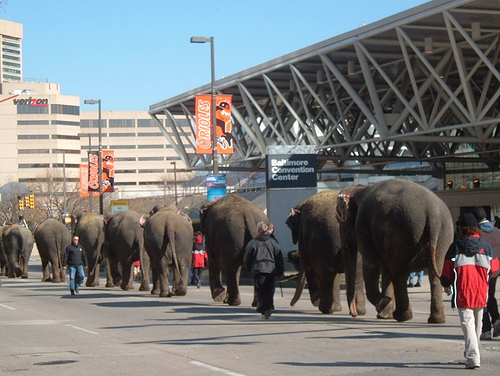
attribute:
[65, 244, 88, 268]
jacket — black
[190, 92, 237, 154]
sign — orange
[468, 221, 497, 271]
jacket — brown